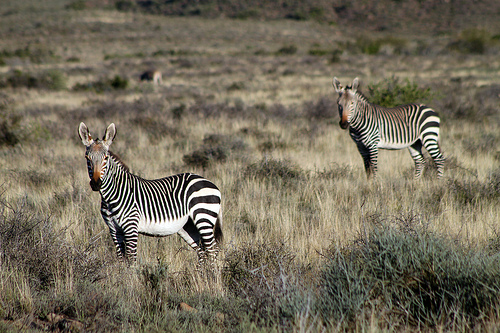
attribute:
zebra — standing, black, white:
[78, 121, 227, 271]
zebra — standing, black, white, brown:
[332, 76, 446, 181]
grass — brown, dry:
[315, 190, 325, 216]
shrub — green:
[368, 75, 431, 108]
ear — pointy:
[333, 75, 345, 92]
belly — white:
[139, 216, 189, 237]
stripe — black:
[188, 195, 221, 211]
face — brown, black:
[337, 98, 355, 129]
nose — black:
[90, 180, 104, 192]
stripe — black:
[405, 102, 409, 125]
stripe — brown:
[406, 106, 410, 122]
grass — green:
[381, 257, 402, 276]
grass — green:
[440, 286, 460, 302]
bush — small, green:
[109, 74, 128, 90]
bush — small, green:
[330, 54, 341, 64]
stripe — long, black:
[138, 177, 149, 224]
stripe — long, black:
[378, 107, 386, 143]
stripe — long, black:
[117, 171, 133, 223]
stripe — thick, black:
[185, 179, 219, 215]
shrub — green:
[284, 9, 312, 20]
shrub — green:
[440, 25, 490, 55]